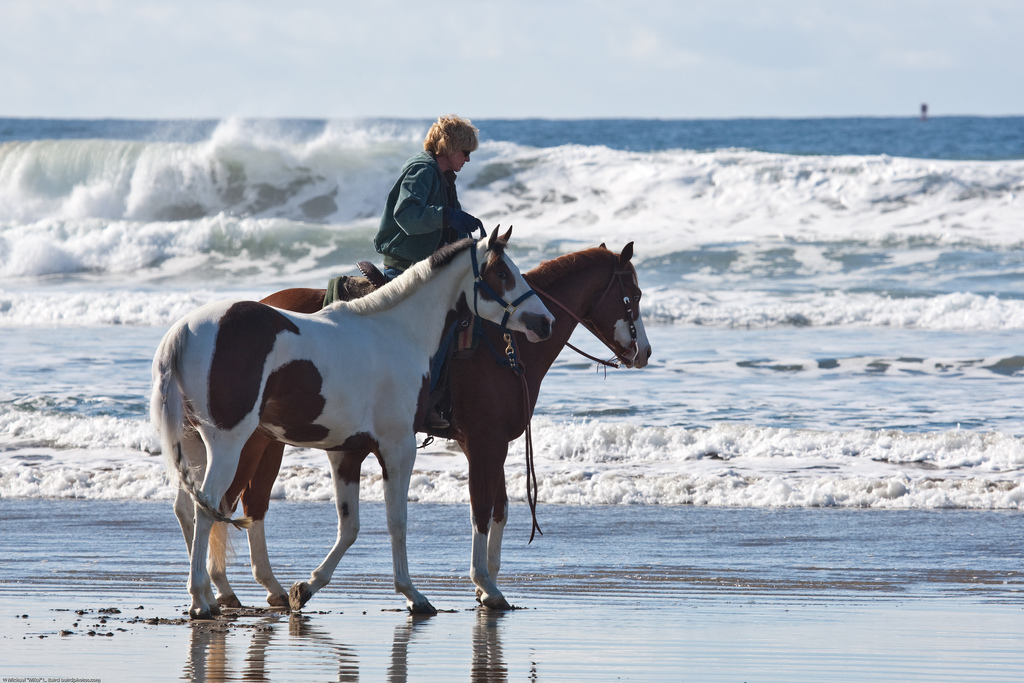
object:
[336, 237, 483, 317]
mane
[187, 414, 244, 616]
legs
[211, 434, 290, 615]
legs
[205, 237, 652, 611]
horse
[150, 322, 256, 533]
tail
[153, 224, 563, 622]
horse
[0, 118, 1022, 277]
waves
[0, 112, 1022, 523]
ocean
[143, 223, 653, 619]
two horses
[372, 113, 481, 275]
woman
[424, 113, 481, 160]
blond hair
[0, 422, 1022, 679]
beach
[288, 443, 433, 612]
front legs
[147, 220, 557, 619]
white/brown horse